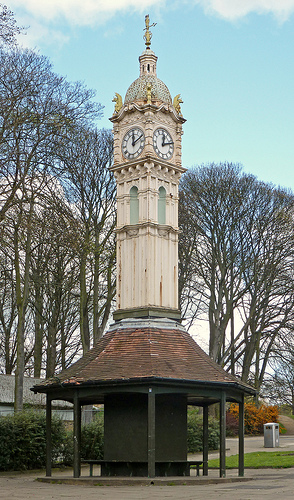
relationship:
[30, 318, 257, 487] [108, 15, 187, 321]
building under tower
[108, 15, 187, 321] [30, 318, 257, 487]
tower on building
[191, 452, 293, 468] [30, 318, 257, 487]
grass near building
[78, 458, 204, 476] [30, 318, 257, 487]
bench in building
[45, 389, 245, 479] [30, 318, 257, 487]
posts supporting building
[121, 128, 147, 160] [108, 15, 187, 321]
clock on tower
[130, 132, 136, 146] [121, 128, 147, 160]
short hand on clock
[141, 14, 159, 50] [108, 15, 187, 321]
weather vain on tower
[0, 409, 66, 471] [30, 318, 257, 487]
bush near building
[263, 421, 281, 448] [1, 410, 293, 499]
trash can on sidewalk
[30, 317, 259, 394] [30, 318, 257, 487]
roof on building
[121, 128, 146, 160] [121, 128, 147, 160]
roman numerals on clock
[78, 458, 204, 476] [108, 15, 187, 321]
bench under tower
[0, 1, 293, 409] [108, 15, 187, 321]
trees behind tower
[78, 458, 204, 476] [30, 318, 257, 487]
bench under building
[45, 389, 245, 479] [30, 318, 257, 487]
posts under building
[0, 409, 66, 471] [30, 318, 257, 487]
bush next to building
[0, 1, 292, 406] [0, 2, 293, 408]
clouds in sky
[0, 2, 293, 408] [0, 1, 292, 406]
sky has clouds